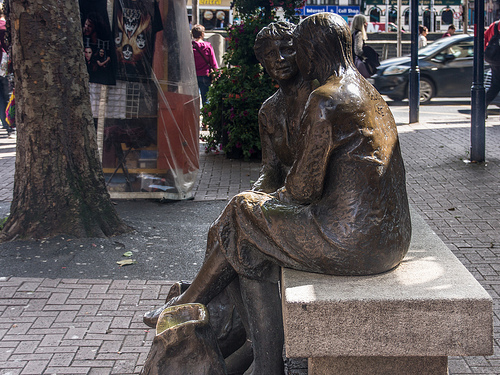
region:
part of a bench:
[432, 282, 446, 307]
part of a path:
[441, 198, 446, 213]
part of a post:
[474, 108, 484, 121]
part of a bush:
[233, 118, 239, 133]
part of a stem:
[75, 182, 103, 215]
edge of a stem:
[58, 149, 70, 163]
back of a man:
[388, 184, 393, 186]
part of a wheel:
[422, 78, 434, 93]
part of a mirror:
[446, 43, 448, 53]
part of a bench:
[423, 310, 439, 327]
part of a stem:
[101, 200, 127, 211]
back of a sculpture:
[359, 209, 363, 227]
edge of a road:
[82, 316, 97, 339]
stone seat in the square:
[298, 280, 485, 342]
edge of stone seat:
[321, 343, 396, 363]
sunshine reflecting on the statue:
[320, 101, 420, 195]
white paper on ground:
[451, 148, 495, 177]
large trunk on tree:
[5, 195, 160, 261]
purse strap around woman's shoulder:
[185, 36, 218, 78]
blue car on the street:
[379, 30, 499, 72]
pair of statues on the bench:
[242, 23, 414, 277]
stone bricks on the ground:
[46, 291, 109, 336]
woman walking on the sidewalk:
[177, 18, 230, 91]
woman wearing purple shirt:
[190, 23, 222, 131]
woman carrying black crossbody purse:
[188, 21, 223, 132]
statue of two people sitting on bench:
[142, 12, 497, 373]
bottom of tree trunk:
[1, 0, 137, 245]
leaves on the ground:
[114, 250, 136, 267]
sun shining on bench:
[283, 283, 315, 308]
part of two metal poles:
[406, 0, 491, 170]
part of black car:
[368, 30, 492, 105]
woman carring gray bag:
[347, 12, 382, 80]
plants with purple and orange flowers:
[198, 0, 306, 166]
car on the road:
[373, 19, 495, 102]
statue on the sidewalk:
[144, 8, 449, 373]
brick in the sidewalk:
[47, 290, 70, 309]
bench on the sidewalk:
[256, 170, 498, 370]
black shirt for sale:
[108, 0, 161, 82]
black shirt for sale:
[72, 0, 120, 82]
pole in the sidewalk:
[457, 0, 490, 167]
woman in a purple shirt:
[185, 36, 224, 76]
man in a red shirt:
[478, 19, 496, 46]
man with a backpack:
[486, 25, 498, 57]